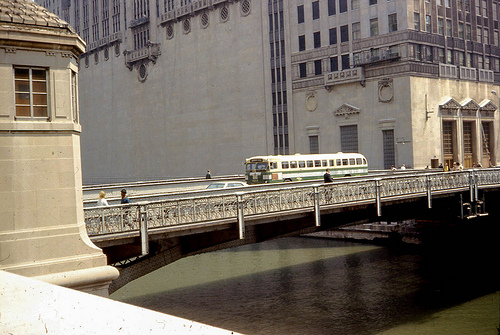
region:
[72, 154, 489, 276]
a metal bridge over water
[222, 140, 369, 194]
a bus crossing a bridge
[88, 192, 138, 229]
two people walking on a bridge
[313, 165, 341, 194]
a man crossing a bridge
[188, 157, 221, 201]
a person crossing a bridge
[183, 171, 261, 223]
a car driving across a bridge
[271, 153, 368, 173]
a row of windows in a bus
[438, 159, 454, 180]
a person wearing a yellow shirt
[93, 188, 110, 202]
a woman with blonde hair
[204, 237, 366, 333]
green water under a bridge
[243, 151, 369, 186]
green and white bus going over a bridge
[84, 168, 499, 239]
side railing on the sides of the bridge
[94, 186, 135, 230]
people walking across the bridge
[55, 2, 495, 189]
large building near the bridge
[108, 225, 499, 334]
water under the bridge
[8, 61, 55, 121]
window in a building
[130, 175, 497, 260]
columns holding the bridge up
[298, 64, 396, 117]
decorative designs on the building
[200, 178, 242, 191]
car crossing the bridge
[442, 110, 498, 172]
door in front of the building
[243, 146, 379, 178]
bus going over bridge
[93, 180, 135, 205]
people going over bridge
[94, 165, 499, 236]
bridge over the water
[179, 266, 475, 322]
water under the bridge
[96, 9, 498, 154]
building near the bridge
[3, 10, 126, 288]
stone structure near bridge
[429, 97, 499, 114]
triangular structures on building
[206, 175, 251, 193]
vehicle going over bridge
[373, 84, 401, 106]
circular structure on building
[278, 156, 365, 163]
windows on the bus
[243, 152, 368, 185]
A long mostly white bus on a bridge.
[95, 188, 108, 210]
A blonde person on a bridge walking.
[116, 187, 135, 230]
A dark haired person walking by a blonde haired person on a bridge.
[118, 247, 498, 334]
A black shadow under the bridge on the green water.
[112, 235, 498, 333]
All the green water under the bridge.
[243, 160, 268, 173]
Front glass window of a bus.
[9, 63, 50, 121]
Eight panes on a window to the left of a bridge.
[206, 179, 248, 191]
Barely visible top of a car in front of a bus on a bridge.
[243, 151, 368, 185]
A mostly white and green bus on a bridge.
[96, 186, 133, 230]
A brunette and blonde walking on a bridge beside each other.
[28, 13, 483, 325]
photograph of a small city bridge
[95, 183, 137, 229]
people walking across bridge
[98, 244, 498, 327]
shadow of bridge cast on water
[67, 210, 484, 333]
water below bridge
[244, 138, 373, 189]
green and white bus on bridge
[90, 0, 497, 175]
large white city building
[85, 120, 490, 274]
bridge built over water for cars and people to cross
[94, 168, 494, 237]
decorative side rails on bridge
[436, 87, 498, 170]
three large tall decorative windows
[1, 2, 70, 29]
decorative blck shingled roof